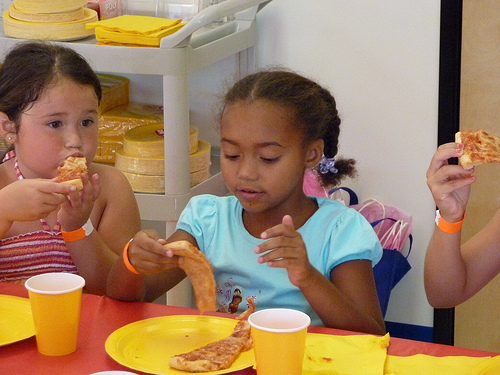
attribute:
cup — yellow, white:
[242, 302, 311, 373]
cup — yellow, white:
[21, 267, 88, 358]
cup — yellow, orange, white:
[24, 272, 86, 359]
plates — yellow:
[105, 114, 215, 198]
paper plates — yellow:
[120, 120, 201, 156]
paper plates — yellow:
[110, 149, 216, 170]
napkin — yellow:
[303, 331, 391, 373]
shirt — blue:
[174, 194, 384, 328]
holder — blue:
[318, 155, 337, 177]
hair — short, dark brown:
[0, 40, 102, 130]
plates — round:
[110, 117, 215, 196]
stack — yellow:
[84, 13, 185, 46]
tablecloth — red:
[1, 280, 498, 372]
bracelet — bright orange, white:
[432, 209, 467, 235]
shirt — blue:
[202, 220, 287, 325]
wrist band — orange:
[119, 230, 138, 281]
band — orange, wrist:
[418, 209, 479, 237]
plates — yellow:
[124, 281, 231, 368]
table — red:
[83, 297, 120, 329]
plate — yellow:
[103, 315, 260, 373]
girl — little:
[100, 63, 387, 334]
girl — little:
[0, 37, 142, 295]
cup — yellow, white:
[248, 305, 310, 373]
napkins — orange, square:
[81, 11, 188, 46]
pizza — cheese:
[162, 236, 219, 320]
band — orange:
[55, 218, 98, 246]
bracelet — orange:
[116, 243, 150, 262]